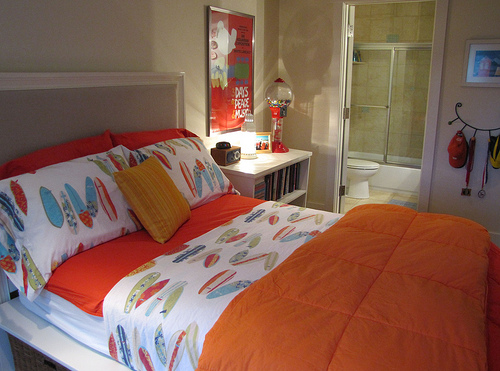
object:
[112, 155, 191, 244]
pillows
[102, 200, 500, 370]
comforter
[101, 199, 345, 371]
sheets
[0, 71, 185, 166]
board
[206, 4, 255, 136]
poster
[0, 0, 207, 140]
wall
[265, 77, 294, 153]
machine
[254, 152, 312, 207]
shelves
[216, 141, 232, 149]
radio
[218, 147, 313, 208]
table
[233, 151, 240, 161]
time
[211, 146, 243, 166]
clock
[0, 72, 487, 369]
bed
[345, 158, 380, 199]
toilet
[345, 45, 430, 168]
door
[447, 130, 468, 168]
hat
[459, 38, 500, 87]
picture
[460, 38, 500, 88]
frame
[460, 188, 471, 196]
metal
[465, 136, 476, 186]
ribbon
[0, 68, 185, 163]
headboard